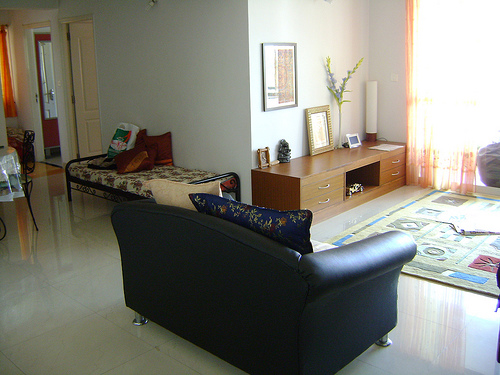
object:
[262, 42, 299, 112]
mirror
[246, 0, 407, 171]
wall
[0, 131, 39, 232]
chair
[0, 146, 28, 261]
tablecloth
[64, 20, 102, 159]
door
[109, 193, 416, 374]
couch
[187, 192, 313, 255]
pillow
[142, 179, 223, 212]
pillow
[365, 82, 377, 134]
candle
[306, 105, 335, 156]
frame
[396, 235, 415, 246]
light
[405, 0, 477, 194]
curtains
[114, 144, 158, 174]
pillow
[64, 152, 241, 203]
bench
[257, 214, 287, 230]
pattern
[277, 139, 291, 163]
figurine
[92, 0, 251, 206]
wall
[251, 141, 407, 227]
table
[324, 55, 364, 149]
flower